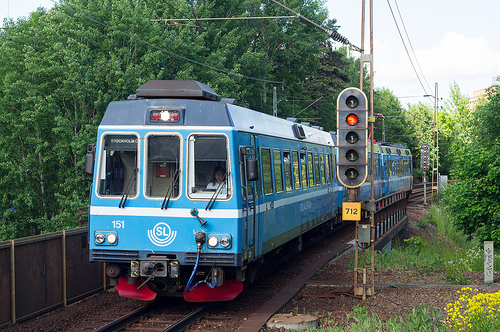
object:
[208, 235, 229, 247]
headlight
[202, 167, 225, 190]
person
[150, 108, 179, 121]
headlight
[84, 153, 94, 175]
mirror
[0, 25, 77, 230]
tree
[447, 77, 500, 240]
tree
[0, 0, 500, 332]
woods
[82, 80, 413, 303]
train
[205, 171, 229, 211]
windshield wiper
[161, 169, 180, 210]
windshield wiper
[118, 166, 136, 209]
windshield wiper